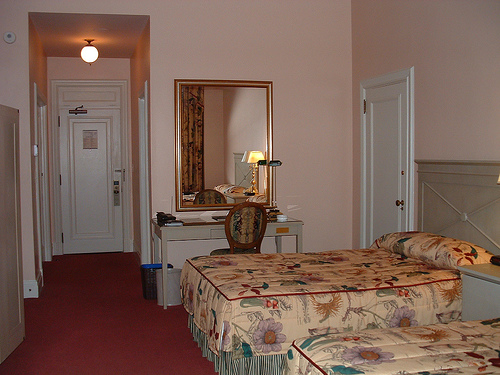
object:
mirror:
[169, 73, 282, 216]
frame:
[172, 78, 276, 213]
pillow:
[366, 221, 499, 274]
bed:
[164, 226, 500, 375]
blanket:
[178, 249, 456, 338]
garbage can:
[138, 257, 171, 308]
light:
[76, 40, 102, 68]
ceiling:
[30, 13, 143, 62]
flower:
[460, 336, 499, 370]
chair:
[215, 195, 275, 256]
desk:
[144, 208, 312, 318]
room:
[3, 4, 500, 373]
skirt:
[175, 316, 294, 374]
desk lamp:
[258, 156, 288, 222]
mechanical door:
[47, 75, 138, 258]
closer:
[64, 101, 91, 120]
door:
[353, 74, 416, 247]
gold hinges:
[53, 110, 70, 253]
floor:
[16, 296, 199, 371]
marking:
[271, 225, 294, 235]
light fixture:
[76, 34, 100, 48]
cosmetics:
[185, 208, 228, 223]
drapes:
[179, 83, 209, 190]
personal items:
[151, 211, 291, 225]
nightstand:
[453, 256, 499, 325]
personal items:
[472, 253, 500, 278]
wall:
[147, 4, 356, 253]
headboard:
[410, 153, 500, 256]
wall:
[412, 3, 500, 160]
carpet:
[6, 237, 208, 373]